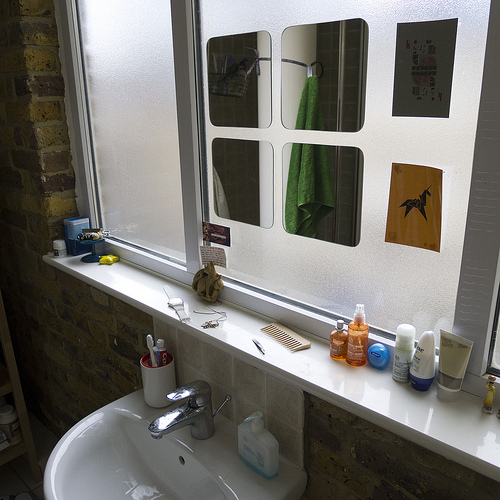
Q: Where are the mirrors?
A: On the wall.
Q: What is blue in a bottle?
A: Soap.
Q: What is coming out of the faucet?
A: It is turned off.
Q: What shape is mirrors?
A: Square.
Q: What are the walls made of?
A: Brick and tiles.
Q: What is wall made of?
A: Brick.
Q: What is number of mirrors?
A: Four.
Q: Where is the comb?
A: On shelf.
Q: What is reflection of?
A: Green towel.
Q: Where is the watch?
A: On white ledge.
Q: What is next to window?
A: Toiletries.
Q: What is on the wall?
A: Mirrors.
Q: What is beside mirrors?
A: Pictures.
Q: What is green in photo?
A: Towel.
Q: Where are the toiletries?
A: White counter.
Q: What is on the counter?
A: Toiletries.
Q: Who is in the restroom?
A: Nobody.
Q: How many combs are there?
A: One.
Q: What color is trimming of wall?
A: White.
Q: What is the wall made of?
A: Brick.